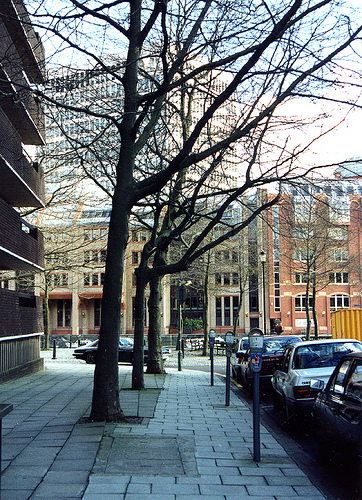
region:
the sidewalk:
[164, 418, 212, 483]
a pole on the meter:
[251, 382, 264, 451]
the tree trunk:
[97, 354, 120, 409]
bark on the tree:
[97, 324, 116, 365]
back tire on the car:
[80, 348, 97, 366]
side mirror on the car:
[304, 374, 323, 391]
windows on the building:
[294, 294, 309, 311]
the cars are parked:
[227, 312, 359, 465]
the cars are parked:
[219, 311, 340, 466]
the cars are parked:
[218, 317, 339, 452]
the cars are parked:
[207, 306, 353, 462]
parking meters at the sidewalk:
[172, 293, 279, 479]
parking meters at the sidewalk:
[195, 309, 272, 478]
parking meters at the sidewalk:
[196, 314, 268, 481]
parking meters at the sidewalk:
[202, 314, 288, 483]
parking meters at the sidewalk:
[196, 308, 277, 486]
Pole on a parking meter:
[245, 368, 268, 473]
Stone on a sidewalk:
[63, 422, 200, 498]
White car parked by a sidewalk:
[268, 332, 359, 415]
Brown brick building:
[242, 184, 360, 330]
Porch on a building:
[3, 283, 50, 339]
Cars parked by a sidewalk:
[222, 328, 361, 476]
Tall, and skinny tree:
[194, 251, 221, 355]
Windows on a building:
[267, 205, 345, 339]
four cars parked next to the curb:
[228, 336, 357, 488]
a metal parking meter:
[244, 325, 267, 460]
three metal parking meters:
[207, 327, 269, 465]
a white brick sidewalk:
[162, 388, 227, 471]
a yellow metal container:
[327, 302, 360, 338]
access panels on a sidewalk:
[97, 427, 192, 477]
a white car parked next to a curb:
[267, 334, 360, 423]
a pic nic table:
[214, 337, 224, 358]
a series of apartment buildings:
[45, 186, 360, 343]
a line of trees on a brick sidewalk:
[42, 1, 332, 425]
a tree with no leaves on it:
[44, 1, 225, 425]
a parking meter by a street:
[244, 328, 269, 460]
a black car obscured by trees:
[67, 332, 168, 367]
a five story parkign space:
[0, 8, 53, 374]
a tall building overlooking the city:
[41, 60, 235, 194]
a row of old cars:
[231, 335, 360, 457]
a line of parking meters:
[198, 328, 274, 461]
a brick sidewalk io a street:
[0, 354, 309, 495]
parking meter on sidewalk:
[245, 323, 266, 464]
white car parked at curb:
[269, 336, 360, 424]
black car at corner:
[72, 332, 174, 361]